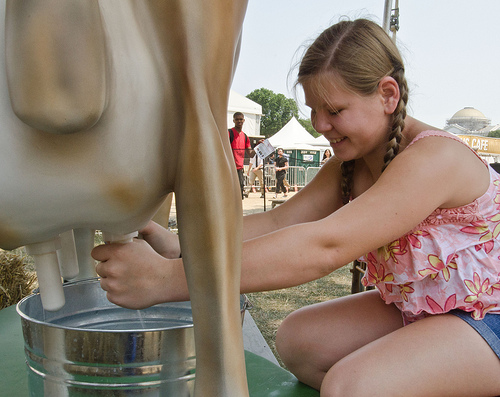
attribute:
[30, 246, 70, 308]
udder — plastic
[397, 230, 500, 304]
shirt — white, colorful, pink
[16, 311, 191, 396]
bucket — silver, metal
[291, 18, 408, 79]
hair — braided, blonde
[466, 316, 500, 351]
shorts — blue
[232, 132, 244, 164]
top — red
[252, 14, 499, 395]
girl — laughing, content, amused, happy, milking, smiling, squatting, practicing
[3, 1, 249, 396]
cow — bronze, fake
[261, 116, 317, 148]
tent — white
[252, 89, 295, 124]
tree — tall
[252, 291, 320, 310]
grass — short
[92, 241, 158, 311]
hand — squeezing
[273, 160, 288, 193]
outfit — black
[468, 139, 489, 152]
writting — white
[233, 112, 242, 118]
hair — brown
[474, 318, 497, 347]
jeans — blue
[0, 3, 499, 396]
photo — outdoor